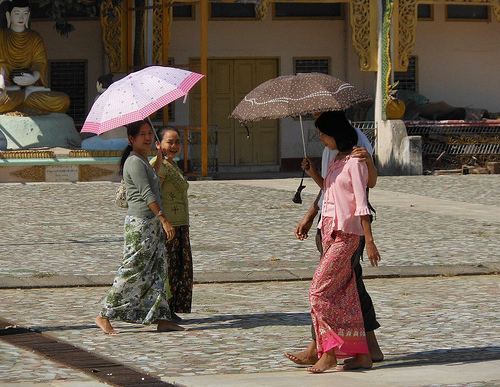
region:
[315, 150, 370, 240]
woman is wearing a pink sweater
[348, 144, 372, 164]
a man's hand is on the woman'e shoulder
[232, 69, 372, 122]
the woman is holding brown umbrella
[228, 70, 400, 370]
a man and woman walk under an open umbrella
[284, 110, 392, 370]
the man and woman are barefoot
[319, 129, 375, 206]
the man is wearing a white shirt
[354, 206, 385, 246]
the woman's sweater has 3/4 length sleeves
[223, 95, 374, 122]
there are ruffles along the edge of the brown umbrella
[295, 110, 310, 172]
the woman is holding the umbrella handle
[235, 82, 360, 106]
there is a white design that circles the brown umbrella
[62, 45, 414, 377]
Four people walking on the street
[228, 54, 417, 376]
A couple walking to the left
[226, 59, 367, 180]
Umbrella is brown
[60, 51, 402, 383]
People have bare feet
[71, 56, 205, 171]
Umbrella is pink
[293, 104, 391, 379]
Woman wears a pink sweeter and long skirt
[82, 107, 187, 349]
Woman wears green jacket and long skirt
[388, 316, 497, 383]
Shadow cast on ground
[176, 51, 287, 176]
Big yellow door on the background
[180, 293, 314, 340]
Shadows on floor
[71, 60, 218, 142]
A PINK AND WHITE UMBRELLA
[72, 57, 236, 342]
TWO WOMEN WITH AN UMBRELLA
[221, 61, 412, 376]
MAN AND WOMAN WITH AN UMBRELLA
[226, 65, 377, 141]
A BROWN UMBRELLA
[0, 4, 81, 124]
A STATUE IN THE LEFT CORNER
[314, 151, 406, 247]
A PINK LADIES SWEATER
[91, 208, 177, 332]
LONG GREEN AND WHITE SKIRT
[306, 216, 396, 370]
A LONG PINK SKIRT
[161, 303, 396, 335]
A SHADOW ON THE GROUND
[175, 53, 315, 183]
DOORS IN THE BACKGROUND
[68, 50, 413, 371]
Four persons walking in the street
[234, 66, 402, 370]
Man holds an umbrella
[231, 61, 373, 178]
Umbrella is brown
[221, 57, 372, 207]
Umbrellas has paterns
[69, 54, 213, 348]
Two women wearing long dresses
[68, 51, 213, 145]
Pink umbrella hold by a woman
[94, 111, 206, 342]
Women wearing patterned skirts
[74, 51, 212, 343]
two Asian ladies walking under a pink umbrella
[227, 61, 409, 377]
an Asian couple walking under a brown umbrella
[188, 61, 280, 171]
cream colored double doors to a building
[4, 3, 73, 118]
a large religious statue of a person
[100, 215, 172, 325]
a woman's white and green floral skirt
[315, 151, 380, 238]
a woman's pink blouse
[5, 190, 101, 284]
the ground made of bricks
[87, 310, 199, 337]
a woman's bare feet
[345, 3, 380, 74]
a light yellow decorative piece on a building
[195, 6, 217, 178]
a yellow pole outside a building